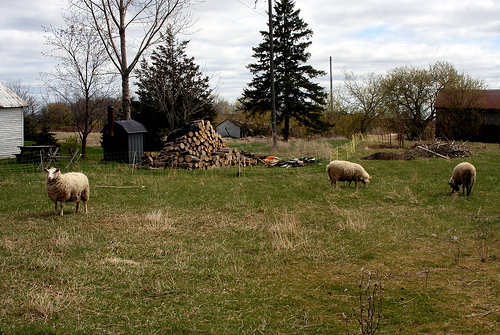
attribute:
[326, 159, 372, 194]
sheep — white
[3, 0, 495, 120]
clouds — white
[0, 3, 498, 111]
sky — cloudy